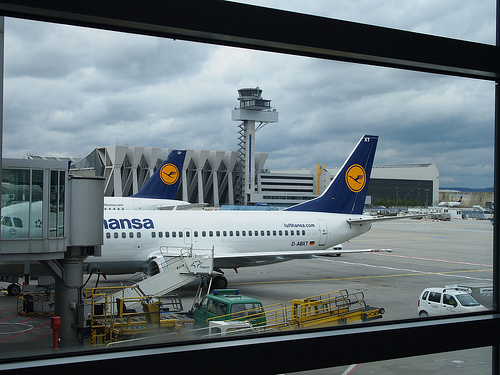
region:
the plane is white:
[12, 132, 389, 300]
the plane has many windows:
[98, 224, 313, 244]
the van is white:
[417, 280, 495, 329]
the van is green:
[178, 290, 271, 337]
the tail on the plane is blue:
[284, 132, 377, 219]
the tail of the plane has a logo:
[283, 130, 380, 224]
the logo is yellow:
[341, 160, 368, 201]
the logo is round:
[340, 161, 374, 201]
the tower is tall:
[228, 72, 279, 203]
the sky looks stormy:
[1, 0, 498, 191]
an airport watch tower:
[228, 80, 283, 126]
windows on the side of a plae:
[171, 230, 305, 237]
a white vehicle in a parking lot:
[408, 279, 483, 316]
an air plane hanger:
[375, 155, 450, 217]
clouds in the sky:
[65, 98, 133, 138]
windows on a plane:
[3, 211, 21, 227]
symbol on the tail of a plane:
[342, 159, 366, 199]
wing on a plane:
[226, 246, 411, 261]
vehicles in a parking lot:
[385, 199, 488, 229]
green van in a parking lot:
[183, 288, 265, 319]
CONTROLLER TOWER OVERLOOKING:
[238, 80, 270, 200]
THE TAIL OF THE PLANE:
[326, 132, 406, 229]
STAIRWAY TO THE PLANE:
[138, 250, 223, 301]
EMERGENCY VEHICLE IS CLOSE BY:
[198, 290, 273, 332]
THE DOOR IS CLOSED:
[310, 212, 349, 253]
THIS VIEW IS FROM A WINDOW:
[19, 5, 490, 367]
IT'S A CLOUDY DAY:
[293, 65, 488, 167]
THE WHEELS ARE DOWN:
[5, 280, 26, 301]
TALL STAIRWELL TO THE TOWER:
[236, 117, 252, 216]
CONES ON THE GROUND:
[416, 209, 450, 234]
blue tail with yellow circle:
[287, 125, 389, 213]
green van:
[182, 277, 269, 327]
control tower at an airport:
[229, 75, 280, 204]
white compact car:
[409, 282, 488, 324]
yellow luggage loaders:
[89, 282, 389, 349]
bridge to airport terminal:
[0, 154, 110, 347]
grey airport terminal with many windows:
[75, 74, 472, 211]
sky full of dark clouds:
[10, 23, 242, 148]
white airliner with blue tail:
[0, 129, 404, 289]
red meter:
[43, 311, 70, 355]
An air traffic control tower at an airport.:
[228, 81, 278, 202]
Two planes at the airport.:
[10, 132, 381, 282]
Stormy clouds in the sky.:
[2, 35, 487, 145]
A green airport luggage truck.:
[85, 290, 265, 330]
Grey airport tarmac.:
[386, 222, 486, 272]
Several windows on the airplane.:
[106, 230, 302, 236]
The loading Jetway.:
[5, 155, 105, 255]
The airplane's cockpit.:
[0, 201, 40, 237]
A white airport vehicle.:
[412, 285, 484, 315]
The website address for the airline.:
[280, 220, 317, 227]